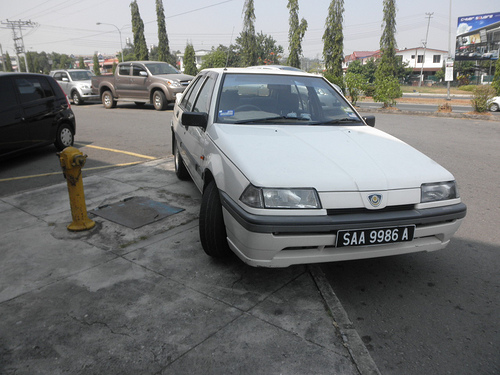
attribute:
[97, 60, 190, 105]
truck — gray, brown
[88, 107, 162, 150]
street — black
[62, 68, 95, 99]
car — silver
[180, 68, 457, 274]
car — white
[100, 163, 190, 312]
curb — cement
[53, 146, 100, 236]
hydrant — yellow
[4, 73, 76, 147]
van — black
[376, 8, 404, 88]
tree — green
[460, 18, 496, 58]
sign — blue, large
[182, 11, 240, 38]
sky — hazy, blue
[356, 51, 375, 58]
roof — red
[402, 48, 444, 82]
house — white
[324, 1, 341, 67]
tree — tall